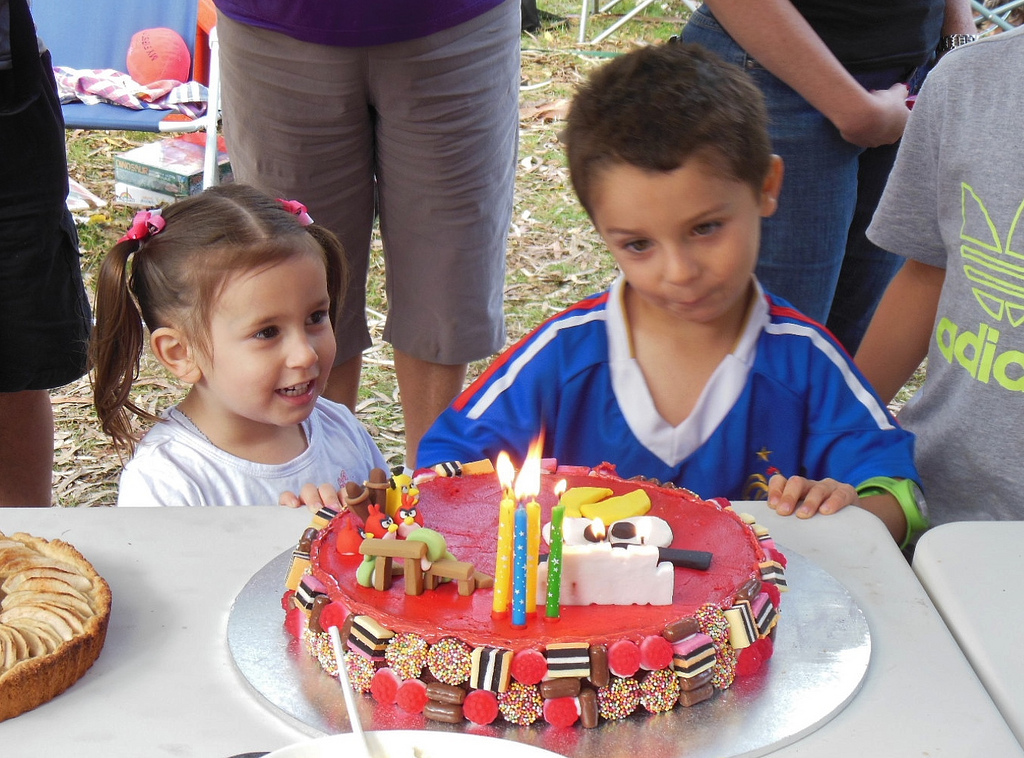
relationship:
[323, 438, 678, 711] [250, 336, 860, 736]
animals on a cake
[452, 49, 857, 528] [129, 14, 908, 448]
person standing outside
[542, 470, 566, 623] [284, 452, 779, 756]
candles on cake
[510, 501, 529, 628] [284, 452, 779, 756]
candle on cake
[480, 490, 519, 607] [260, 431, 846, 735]
candle on cake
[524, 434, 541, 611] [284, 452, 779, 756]
candle on cake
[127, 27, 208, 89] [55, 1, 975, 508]
balloon on floor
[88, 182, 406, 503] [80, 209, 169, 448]
girl with pigtail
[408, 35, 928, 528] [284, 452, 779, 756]
boy looking at cake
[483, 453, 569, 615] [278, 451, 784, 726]
candles on birthday cake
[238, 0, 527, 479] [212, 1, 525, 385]
onlooker with capris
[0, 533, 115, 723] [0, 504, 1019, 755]
pastry on table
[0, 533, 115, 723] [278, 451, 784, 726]
pastry next to birthday cake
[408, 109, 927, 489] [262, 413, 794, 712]
boy in front of birthday cake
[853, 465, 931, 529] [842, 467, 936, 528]
watch on wrist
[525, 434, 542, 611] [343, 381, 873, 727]
candle on cake